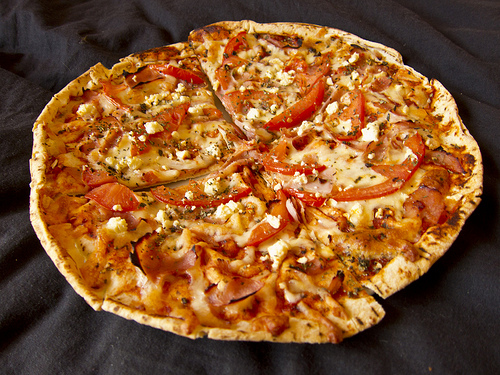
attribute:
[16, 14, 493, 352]
pizza — round, sliced, brown, green, red, whole pie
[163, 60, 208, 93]
tomato — sliced thinly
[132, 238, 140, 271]
black mark — spotted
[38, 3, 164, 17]
blanket — black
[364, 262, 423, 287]
crust — thin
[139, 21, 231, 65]
crust edge — burnt